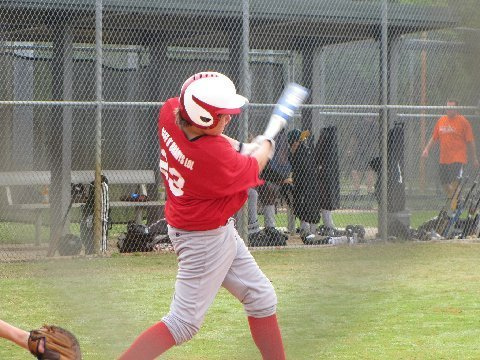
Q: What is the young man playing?
A: Baseball.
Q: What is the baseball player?
A: Hitting ball.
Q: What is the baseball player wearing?
A: Red and grey uniform.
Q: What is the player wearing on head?
A: Helmet.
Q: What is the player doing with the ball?
A: Swinging.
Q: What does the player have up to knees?
A: Red socks.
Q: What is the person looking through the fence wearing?
A: Orange and white shirt.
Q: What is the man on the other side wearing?
A: Shorts and shirt.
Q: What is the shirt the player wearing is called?
A: Jersey.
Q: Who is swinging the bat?
A: A baseball player.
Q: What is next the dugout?
A: A gray metal fence.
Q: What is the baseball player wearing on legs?
A: Red long socks.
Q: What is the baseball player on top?
A: A red uniform.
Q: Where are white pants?
A: On a person in the picture.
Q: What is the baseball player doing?
A: Swinging the bat.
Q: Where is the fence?
A: In front of dugout.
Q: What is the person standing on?
A: Field of green grass.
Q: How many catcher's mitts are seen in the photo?
A: One.